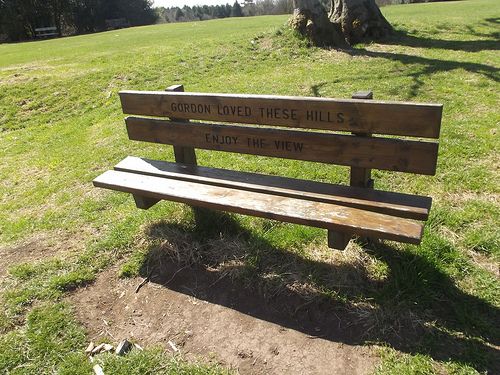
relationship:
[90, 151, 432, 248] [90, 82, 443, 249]
seat of bench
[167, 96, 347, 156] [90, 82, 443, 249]
writing on bench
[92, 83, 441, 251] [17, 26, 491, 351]
bench in park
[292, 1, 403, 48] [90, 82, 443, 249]
stump behind bench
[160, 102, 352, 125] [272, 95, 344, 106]
words in wood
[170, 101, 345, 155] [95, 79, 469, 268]
message in wood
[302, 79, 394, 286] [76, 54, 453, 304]
support for bench